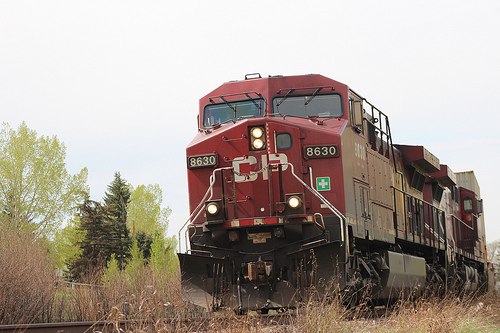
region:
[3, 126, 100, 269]
Large light green tree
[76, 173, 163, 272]
Large dark green tree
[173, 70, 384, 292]
Front of the train is red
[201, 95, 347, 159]
The train has two front windows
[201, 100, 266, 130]
Front window on a train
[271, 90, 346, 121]
Front window on a train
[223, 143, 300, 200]
The letters "CP" is on front of the train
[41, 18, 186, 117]
Large body of overcast skies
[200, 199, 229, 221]
Front light on a train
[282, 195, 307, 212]
Front light on a train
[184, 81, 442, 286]
red train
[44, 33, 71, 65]
white clouds in blue sky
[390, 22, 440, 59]
white clouds in blue sky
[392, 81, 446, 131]
white clouds in blue sky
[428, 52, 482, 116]
white clouds in blue sky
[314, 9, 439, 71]
white clouds in blue sky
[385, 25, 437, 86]
white clouds in blue sky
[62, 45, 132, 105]
white clouds in blue sky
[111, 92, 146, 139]
white clouds in blue sky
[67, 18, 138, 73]
white clouds in blue sky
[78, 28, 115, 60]
white clouds in blue sky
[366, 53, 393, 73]
white clouds in blue sky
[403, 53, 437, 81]
white clouds in blue sky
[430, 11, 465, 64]
white clouds in blue sky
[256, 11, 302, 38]
white clouds in blue sky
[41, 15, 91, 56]
white clouds in blue sky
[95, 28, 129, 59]
white clouds in blue sky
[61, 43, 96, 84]
white clouds in blue sky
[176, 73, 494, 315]
A red train traveling down tracks.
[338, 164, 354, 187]
the trainn is red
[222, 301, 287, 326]
the train is on the track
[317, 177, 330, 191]
the sign is green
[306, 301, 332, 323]
the weeds are dead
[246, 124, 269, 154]
the lights are on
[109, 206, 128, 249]
tree is dark green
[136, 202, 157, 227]
tree is lime green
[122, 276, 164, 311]
the weeds are tan